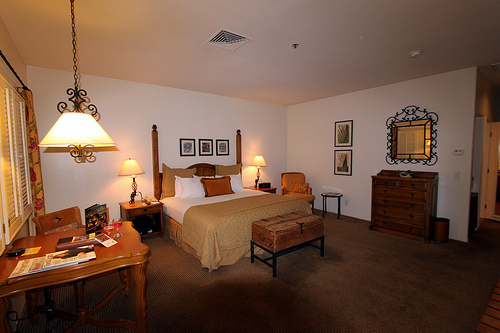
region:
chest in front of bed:
[250, 218, 355, 265]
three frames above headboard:
[173, 136, 237, 161]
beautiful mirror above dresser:
[380, 106, 439, 169]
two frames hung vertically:
[330, 118, 359, 184]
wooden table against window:
[10, 200, 170, 317]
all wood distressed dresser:
[365, 159, 461, 248]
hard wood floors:
[195, 272, 463, 326]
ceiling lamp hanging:
[40, 58, 115, 162]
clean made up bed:
[166, 171, 285, 205]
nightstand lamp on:
[119, 165, 154, 209]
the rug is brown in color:
[317, 286, 418, 298]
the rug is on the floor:
[248, 271, 415, 308]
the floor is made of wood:
[463, 292, 498, 321]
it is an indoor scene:
[73, 61, 423, 319]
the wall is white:
[249, 101, 279, 150]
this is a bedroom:
[71, 30, 447, 310]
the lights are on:
[36, 79, 328, 231]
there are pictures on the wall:
[163, 132, 245, 154]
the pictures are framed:
[175, 111, 402, 191]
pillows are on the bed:
[152, 141, 292, 221]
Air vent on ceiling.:
[208, 17, 251, 57]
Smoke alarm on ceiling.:
[406, 44, 428, 62]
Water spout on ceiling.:
[280, 37, 312, 53]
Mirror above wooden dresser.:
[386, 103, 440, 168]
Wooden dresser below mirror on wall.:
[368, 161, 433, 237]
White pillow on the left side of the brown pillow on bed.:
[173, 176, 204, 198]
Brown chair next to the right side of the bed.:
[279, 171, 314, 201]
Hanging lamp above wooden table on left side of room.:
[44, 47, 105, 175]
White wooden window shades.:
[0, 94, 35, 239]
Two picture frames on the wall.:
[333, 120, 353, 184]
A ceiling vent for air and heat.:
[208, 26, 258, 58]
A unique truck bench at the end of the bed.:
[248, 200, 337, 254]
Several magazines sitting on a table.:
[8, 235, 121, 277]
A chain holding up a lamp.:
[54, 0, 96, 82]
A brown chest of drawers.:
[359, 163, 443, 245]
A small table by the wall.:
[318, 187, 353, 224]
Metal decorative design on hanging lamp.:
[50, 83, 107, 123]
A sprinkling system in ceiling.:
[283, 38, 304, 50]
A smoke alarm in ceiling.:
[410, 45, 421, 65]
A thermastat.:
[446, 142, 468, 159]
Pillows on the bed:
[156, 160, 248, 200]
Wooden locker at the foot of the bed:
[249, 206, 329, 254]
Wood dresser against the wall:
[367, 166, 439, 246]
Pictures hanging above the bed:
[176, 135, 231, 157]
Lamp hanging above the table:
[38, 89, 119, 164]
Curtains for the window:
[20, 88, 47, 216]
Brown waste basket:
[432, 215, 453, 246]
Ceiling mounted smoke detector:
[409, 48, 421, 60]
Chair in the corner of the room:
[279, 169, 316, 211]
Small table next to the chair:
[321, 191, 344, 218]